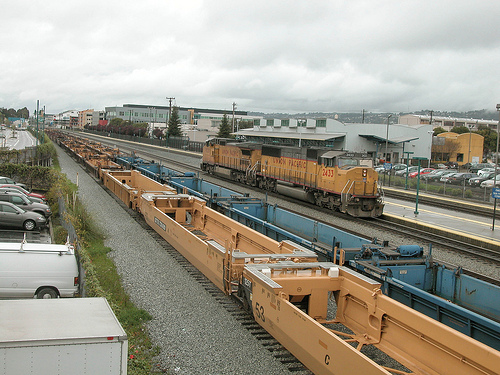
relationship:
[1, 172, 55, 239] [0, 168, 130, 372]
cars in row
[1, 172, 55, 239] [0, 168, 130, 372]
cars in parking lot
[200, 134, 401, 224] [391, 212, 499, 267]
train on tracks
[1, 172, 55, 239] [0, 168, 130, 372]
cars in lot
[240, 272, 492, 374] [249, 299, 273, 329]
train has 53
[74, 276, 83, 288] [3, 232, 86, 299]
tail light on van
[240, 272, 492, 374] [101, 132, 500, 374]
train on tracks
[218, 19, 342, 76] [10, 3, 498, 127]
clouds in sky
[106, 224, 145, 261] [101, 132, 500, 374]
gravel beside tracks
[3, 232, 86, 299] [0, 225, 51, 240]
van in parking  spot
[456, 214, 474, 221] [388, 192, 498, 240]
line on asphalt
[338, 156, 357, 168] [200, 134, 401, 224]
window on train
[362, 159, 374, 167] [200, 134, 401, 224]
window on train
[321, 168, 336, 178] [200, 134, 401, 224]
number on train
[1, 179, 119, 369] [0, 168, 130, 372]
automobiles in parking lot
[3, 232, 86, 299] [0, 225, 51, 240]
van in parking stall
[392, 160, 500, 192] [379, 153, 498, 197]
cars in lot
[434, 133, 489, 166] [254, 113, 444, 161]
business behind building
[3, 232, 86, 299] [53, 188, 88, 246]
van near fence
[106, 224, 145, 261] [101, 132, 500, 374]
gravel near tracks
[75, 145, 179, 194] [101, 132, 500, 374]
train car on tracks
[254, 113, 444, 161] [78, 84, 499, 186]
building on right side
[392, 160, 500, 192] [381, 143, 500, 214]
cars in lot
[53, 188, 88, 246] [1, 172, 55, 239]
fence near cars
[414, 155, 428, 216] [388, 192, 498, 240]
post on road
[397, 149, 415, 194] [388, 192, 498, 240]
post on road